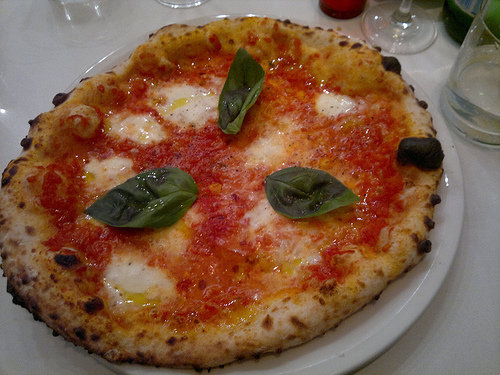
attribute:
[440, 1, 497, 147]
glass — empty, short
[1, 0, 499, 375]
table — white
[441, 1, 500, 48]
bottle — green, glass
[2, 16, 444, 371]
pizza — small, well done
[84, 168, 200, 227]
spinach — green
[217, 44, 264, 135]
spinach — green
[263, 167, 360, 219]
spinach — green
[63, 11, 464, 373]
plate — white, round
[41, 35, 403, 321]
sauce — red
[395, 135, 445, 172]
spot — burned, bubble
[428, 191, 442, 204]
spot — burned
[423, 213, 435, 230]
spot — burned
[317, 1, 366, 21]
cup — red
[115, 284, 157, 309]
grease — yellow